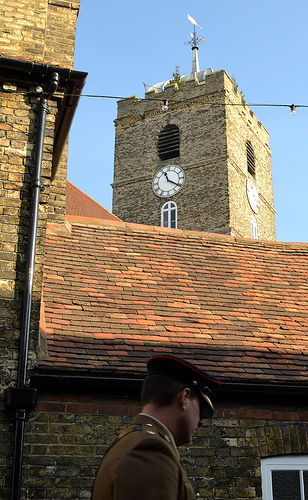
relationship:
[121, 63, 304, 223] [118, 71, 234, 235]
window on building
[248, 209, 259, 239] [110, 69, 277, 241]
window on building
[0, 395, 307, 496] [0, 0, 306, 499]
bricks on house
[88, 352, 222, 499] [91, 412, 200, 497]
man wearing uniform